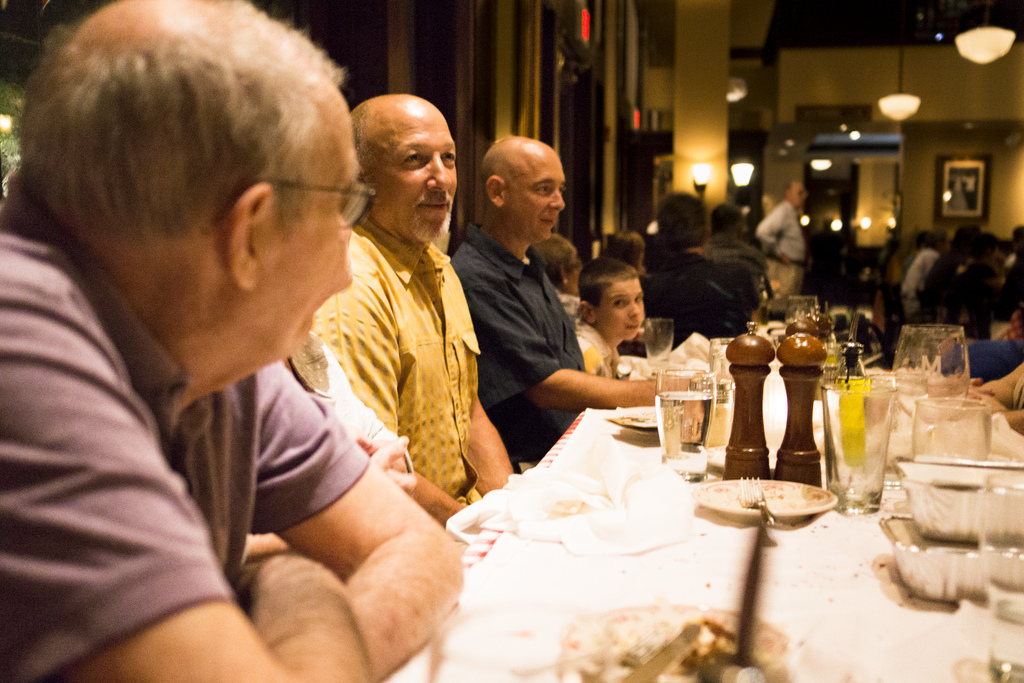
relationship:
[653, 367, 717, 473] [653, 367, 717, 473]
glass of water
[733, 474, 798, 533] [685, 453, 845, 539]
fork on plate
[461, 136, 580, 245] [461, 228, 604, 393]
man wearing shirt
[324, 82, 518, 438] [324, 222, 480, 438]
man wearing shirt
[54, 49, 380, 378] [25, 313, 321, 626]
man wearing shirt